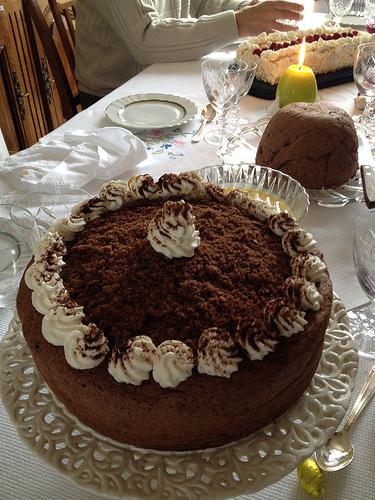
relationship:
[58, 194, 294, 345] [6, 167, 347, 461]
crumbles on cake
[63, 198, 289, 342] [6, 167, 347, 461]
crumbles on cake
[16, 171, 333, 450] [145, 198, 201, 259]
cakes with whip cream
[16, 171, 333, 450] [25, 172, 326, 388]
cakes with whip cream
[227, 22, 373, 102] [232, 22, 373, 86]
cake on top of cake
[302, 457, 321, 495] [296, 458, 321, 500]
chocolate egg in chocolate egg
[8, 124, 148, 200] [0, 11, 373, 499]
napkin on table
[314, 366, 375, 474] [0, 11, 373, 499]
spoon on table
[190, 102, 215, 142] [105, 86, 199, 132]
spoon beside plate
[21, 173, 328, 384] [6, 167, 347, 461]
icing around top of cake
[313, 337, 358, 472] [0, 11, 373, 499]
spoon on top of table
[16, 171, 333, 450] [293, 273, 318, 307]
cakes has vanilla frosting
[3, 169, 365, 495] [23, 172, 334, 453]
plate holds cake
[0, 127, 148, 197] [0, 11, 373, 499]
napkin on table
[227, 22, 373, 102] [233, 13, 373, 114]
cake are on top of cake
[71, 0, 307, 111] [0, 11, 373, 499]
person sitting at table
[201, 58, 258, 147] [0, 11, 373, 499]
glass on table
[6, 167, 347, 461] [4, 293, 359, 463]
cake in plate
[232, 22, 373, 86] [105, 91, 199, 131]
cake in plate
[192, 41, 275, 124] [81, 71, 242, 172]
glass in table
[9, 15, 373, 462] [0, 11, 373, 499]
cakes are in table